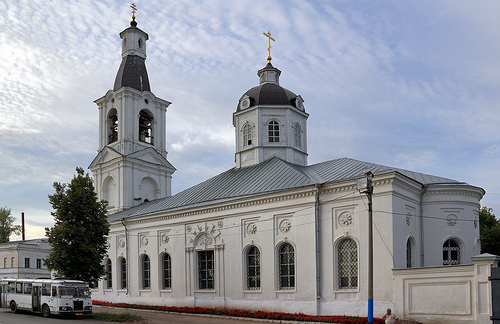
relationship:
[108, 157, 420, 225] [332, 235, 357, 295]
church has window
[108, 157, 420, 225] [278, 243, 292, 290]
church has window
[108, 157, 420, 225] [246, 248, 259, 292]
church has window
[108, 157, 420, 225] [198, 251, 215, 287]
church has window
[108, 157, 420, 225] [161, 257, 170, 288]
church has window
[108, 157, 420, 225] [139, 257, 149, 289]
church has window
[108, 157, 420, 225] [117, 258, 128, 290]
church has window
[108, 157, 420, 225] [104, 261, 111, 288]
church has window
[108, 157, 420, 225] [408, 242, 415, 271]
church has window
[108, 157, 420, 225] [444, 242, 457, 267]
church has window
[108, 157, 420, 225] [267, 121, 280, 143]
church has window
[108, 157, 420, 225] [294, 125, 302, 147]
church has window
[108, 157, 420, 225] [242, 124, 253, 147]
church has window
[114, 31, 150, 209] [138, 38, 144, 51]
belltower has window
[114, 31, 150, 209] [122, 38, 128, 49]
belltower has window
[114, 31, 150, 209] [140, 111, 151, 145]
belltower has window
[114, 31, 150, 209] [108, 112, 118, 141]
belltower has window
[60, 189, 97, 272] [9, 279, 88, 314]
tree by bus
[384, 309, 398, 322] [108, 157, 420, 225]
man near church